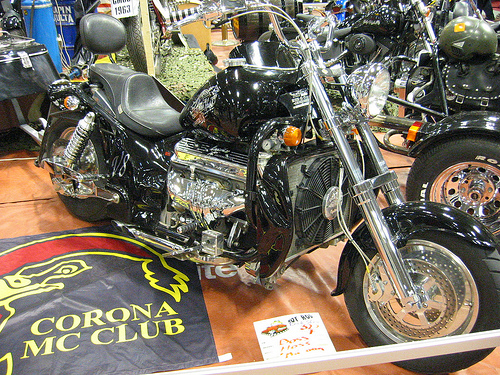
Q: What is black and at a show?
A: A motorcycle.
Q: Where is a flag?
A: Motorcycle club.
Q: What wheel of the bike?
A: Front.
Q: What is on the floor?
A: Flag.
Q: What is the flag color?
A: Black.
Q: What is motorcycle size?
A: Large.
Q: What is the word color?
A: Yellow.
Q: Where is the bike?
A: Ground.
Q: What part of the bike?
A: Wheel.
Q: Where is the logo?
A: Floor.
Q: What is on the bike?
A: A seat.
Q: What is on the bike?
A: A handle.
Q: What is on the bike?
A: Lights.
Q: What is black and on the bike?
A: A wheel.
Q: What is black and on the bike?
A: Leather seat.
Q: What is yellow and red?
A: A logo.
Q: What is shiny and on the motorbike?
A: Silver color.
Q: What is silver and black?
A: A wheel.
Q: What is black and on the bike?
A: A seat.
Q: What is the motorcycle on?
A: Orange carpet.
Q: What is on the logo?
A: A bird.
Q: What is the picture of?
A: Motorcycle.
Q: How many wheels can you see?
A: Three.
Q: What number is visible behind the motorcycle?
A: 1963.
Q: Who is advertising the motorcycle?
A: Corona MC Club.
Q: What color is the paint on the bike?
A: Black.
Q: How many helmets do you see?
A: One.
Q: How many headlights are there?
A: One.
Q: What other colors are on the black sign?
A: Red and yellow.